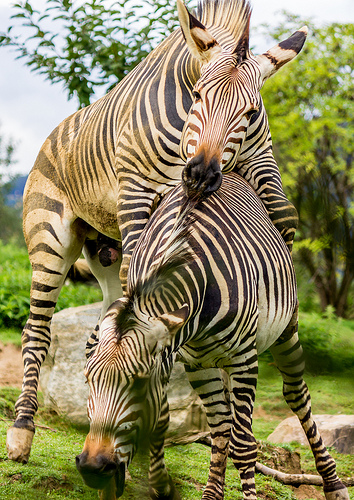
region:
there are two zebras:
[62, 220, 286, 486]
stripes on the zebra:
[235, 407, 258, 459]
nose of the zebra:
[64, 438, 125, 486]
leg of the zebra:
[290, 419, 344, 490]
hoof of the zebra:
[322, 484, 331, 489]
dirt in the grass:
[22, 474, 78, 490]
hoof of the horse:
[8, 423, 38, 460]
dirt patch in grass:
[303, 481, 322, 493]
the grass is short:
[173, 452, 197, 469]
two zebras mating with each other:
[41, 6, 340, 478]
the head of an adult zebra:
[74, 290, 185, 486]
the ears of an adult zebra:
[72, 283, 195, 358]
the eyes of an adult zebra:
[82, 361, 154, 395]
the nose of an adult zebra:
[67, 451, 107, 471]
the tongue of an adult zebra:
[92, 478, 122, 498]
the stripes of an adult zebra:
[200, 230, 274, 292]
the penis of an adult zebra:
[75, 213, 116, 271]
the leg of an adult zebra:
[9, 303, 58, 468]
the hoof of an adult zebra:
[5, 422, 49, 468]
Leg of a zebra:
[0, 195, 76, 475]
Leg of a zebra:
[266, 314, 346, 493]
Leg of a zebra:
[217, 331, 260, 491]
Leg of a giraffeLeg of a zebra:
[270, 323, 349, 476]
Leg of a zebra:
[150, 355, 186, 498]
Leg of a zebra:
[6, 209, 80, 454]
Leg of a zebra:
[90, 267, 135, 433]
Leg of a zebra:
[183, 343, 246, 498]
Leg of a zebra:
[225, 339, 281, 497]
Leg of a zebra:
[275, 306, 344, 495]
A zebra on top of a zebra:
[22, 105, 298, 372]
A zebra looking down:
[44, 346, 157, 480]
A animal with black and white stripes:
[4, 242, 272, 393]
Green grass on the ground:
[125, 421, 236, 496]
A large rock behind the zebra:
[29, 246, 127, 445]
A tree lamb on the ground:
[199, 448, 348, 497]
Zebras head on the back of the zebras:
[155, 61, 265, 216]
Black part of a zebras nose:
[46, 397, 141, 487]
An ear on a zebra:
[151, 303, 190, 335]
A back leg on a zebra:
[276, 323, 344, 498]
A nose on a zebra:
[72, 455, 112, 488]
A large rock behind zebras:
[45, 303, 211, 439]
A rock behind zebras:
[267, 411, 353, 447]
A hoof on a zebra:
[6, 426, 33, 464]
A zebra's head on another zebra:
[175, 0, 305, 196]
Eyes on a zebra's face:
[190, 90, 259, 114]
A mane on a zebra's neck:
[116, 195, 197, 337]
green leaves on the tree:
[266, 17, 353, 228]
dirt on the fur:
[63, 112, 102, 188]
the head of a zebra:
[75, 297, 189, 481]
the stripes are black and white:
[215, 203, 271, 278]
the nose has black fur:
[183, 152, 218, 192]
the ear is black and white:
[258, 26, 308, 74]